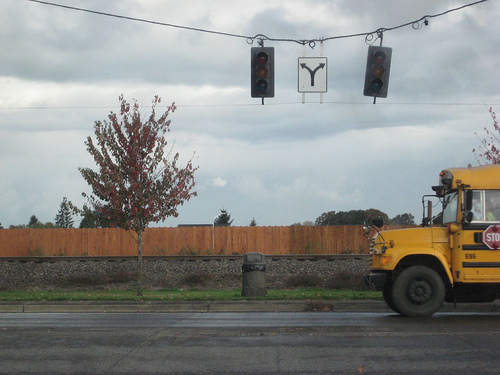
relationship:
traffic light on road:
[358, 40, 395, 105] [229, 300, 370, 335]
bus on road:
[365, 162, 499, 321] [0, 283, 356, 365]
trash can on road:
[242, 252, 267, 297] [1, 310, 498, 374]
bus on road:
[365, 162, 499, 321] [1, 310, 498, 374]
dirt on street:
[115, 325, 375, 337] [0, 313, 499, 373]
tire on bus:
[383, 256, 458, 316] [388, 152, 498, 304]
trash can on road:
[243, 250, 270, 299] [0, 304, 496, 373]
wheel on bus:
[388, 259, 443, 320] [365, 162, 499, 321]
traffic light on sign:
[363, 45, 392, 99] [297, 57, 329, 92]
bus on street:
[365, 162, 499, 321] [0, 313, 499, 373]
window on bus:
[469, 191, 499, 223] [365, 162, 499, 321]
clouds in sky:
[14, 79, 483, 151] [3, 1, 484, 221]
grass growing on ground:
[2, 286, 391, 310] [4, 284, 441, 317]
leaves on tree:
[122, 130, 135, 146] [77, 91, 204, 296]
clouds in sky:
[14, 79, 483, 151] [191, 95, 344, 182]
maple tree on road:
[64, 91, 202, 301] [5, 300, 429, 365]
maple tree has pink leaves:
[64, 91, 202, 301] [147, 122, 154, 133]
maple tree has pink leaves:
[64, 91, 202, 301] [163, 164, 172, 177]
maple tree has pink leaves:
[64, 91, 202, 301] [185, 158, 192, 174]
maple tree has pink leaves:
[64, 91, 202, 301] [94, 120, 102, 139]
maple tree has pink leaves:
[64, 91, 202, 301] [142, 210, 154, 220]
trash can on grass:
[238, 249, 269, 296] [2, 284, 388, 299]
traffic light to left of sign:
[247, 34, 276, 105] [290, 39, 344, 100]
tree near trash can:
[61, 92, 201, 296] [237, 250, 269, 301]